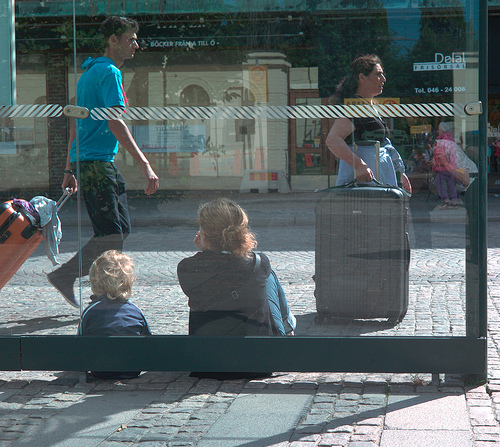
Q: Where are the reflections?
A: Window.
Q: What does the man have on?
A: Shorts.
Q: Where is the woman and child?
A: Pavement.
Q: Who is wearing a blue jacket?
A: A woman.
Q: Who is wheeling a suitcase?
A: A woman.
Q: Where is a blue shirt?
A: On a man.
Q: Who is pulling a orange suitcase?
A: A man.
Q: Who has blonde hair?
A: A child.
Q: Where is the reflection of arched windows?
A: A glass partition.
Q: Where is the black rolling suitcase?
A: The lady holding.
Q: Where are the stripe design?
A: On glass.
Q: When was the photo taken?
A: Daytime.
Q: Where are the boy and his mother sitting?
A: In a bus stop.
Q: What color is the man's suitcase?
A: Orange.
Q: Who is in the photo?
A: A man, two women and a child.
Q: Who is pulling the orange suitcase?
A: The man.